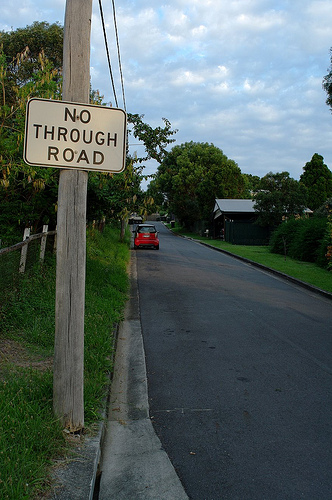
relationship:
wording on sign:
[32, 107, 117, 164] [21, 98, 128, 177]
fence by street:
[2, 223, 62, 276] [132, 223, 331, 497]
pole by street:
[48, 0, 97, 434] [132, 223, 331, 497]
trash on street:
[169, 218, 177, 230] [132, 223, 331, 497]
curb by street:
[90, 225, 164, 499] [132, 223, 331, 497]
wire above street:
[95, 0, 124, 110] [132, 223, 331, 497]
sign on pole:
[21, 98, 128, 177] [48, 0, 97, 434]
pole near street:
[48, 0, 97, 434] [132, 223, 331, 497]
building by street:
[210, 197, 314, 241] [132, 223, 331, 497]